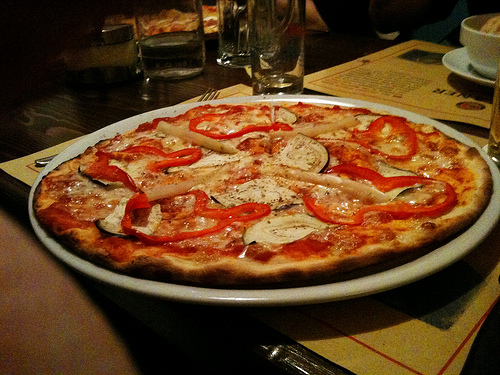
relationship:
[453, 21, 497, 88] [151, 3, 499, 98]
bowl on table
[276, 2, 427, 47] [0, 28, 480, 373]
person sitting at table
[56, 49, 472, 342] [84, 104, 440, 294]
plate with pizza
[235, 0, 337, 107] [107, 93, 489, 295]
glass directly above pizza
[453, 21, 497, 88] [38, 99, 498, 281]
bowl past pizza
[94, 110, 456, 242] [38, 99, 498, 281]
peppers on pizza